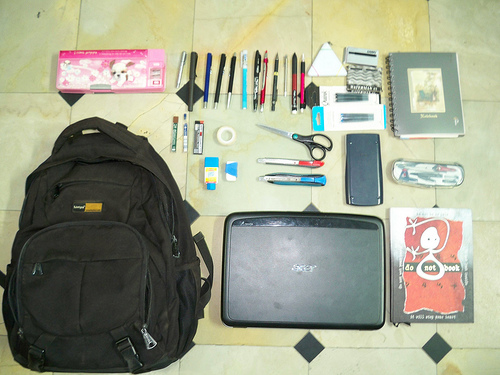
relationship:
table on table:
[213, 122, 239, 147] [1, 4, 478, 369]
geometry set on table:
[55, 43, 165, 97] [213, 122, 239, 147]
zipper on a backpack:
[142, 273, 157, 350] [2, 115, 216, 375]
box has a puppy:
[58, 47, 166, 92] [108, 58, 134, 86]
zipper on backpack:
[135, 275, 162, 352] [2, 115, 216, 370]